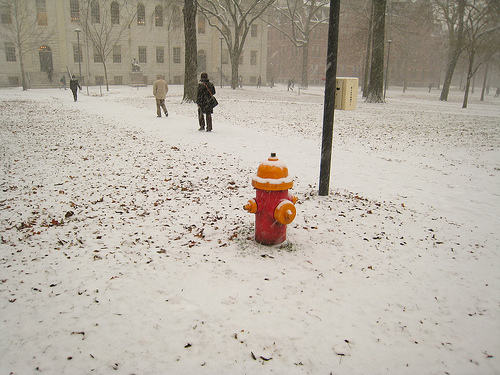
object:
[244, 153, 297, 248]
hydrant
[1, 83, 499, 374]
snow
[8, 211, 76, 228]
leaves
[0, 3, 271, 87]
building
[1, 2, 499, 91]
background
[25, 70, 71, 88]
steps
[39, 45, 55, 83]
door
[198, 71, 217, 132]
man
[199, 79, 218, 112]
bag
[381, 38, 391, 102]
pole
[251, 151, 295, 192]
top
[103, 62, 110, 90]
trunk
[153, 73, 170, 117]
man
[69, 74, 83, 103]
man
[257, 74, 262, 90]
man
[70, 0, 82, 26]
window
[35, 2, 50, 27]
window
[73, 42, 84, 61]
window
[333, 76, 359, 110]
can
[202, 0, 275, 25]
branches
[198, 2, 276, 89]
tree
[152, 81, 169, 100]
jacket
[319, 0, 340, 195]
pole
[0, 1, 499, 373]
outside